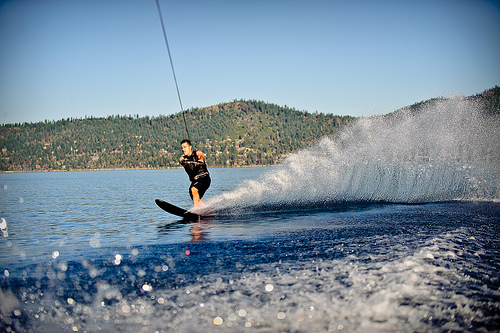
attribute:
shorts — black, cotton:
[183, 171, 211, 198]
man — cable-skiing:
[148, 122, 225, 232]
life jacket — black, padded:
[174, 152, 212, 193]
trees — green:
[5, 130, 305, 151]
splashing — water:
[243, 128, 480, 213]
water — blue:
[5, 175, 493, 331]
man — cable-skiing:
[169, 130, 211, 215]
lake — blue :
[2, 165, 497, 331]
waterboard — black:
[151, 194, 199, 220]